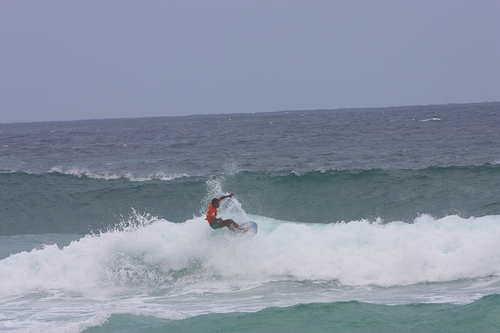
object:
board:
[208, 221, 257, 243]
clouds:
[0, 0, 500, 123]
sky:
[0, 0, 500, 123]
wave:
[0, 192, 500, 333]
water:
[0, 101, 500, 333]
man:
[205, 193, 248, 234]